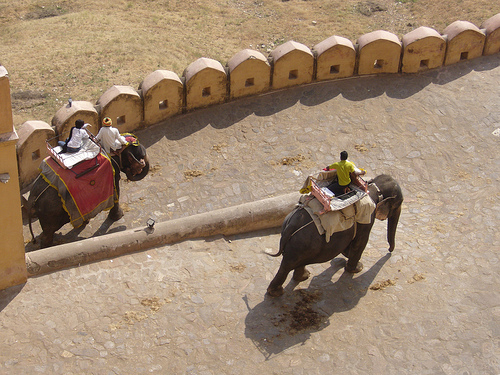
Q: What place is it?
A: It is a walkway.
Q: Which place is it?
A: It is a walkway.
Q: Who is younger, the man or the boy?
A: The boy is younger than the man.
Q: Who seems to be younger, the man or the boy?
A: The boy is younger than the man.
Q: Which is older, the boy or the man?
A: The man is older than the boy.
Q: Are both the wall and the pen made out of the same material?
A: Yes, both the wall and the pen are made of concrete.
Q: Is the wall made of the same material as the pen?
A: Yes, both the wall and the pen are made of concrete.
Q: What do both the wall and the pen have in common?
A: The material, both the wall and the pen are concrete.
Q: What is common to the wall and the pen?
A: The material, both the wall and the pen are concrete.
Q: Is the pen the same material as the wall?
A: Yes, both the pen and the wall are made of cement.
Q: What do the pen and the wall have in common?
A: The material, both the pen and the wall are concrete.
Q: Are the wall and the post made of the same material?
A: No, the wall is made of cement and the post is made of wood.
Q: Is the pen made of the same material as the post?
A: No, the pen is made of cement and the post is made of wood.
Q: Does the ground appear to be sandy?
A: Yes, the ground is sandy.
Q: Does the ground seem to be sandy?
A: Yes, the ground is sandy.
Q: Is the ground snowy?
A: No, the ground is sandy.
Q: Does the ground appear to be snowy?
A: No, the ground is sandy.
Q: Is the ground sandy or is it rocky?
A: The ground is sandy.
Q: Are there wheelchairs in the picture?
A: No, there are no wheelchairs.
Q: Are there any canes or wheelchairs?
A: No, there are no wheelchairs or canes.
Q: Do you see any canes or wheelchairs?
A: No, there are no wheelchairs or canes.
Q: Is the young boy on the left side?
A: Yes, the boy is on the left of the image.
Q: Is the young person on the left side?
A: Yes, the boy is on the left of the image.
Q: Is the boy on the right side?
A: No, the boy is on the left of the image.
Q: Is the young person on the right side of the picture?
A: No, the boy is on the left of the image.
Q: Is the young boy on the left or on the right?
A: The boy is on the left of the image.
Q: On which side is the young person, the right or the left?
A: The boy is on the left of the image.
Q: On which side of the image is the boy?
A: The boy is on the left of the image.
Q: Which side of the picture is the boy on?
A: The boy is on the left of the image.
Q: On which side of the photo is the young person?
A: The boy is on the left of the image.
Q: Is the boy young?
A: Yes, the boy is young.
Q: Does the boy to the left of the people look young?
A: Yes, the boy is young.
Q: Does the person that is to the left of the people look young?
A: Yes, the boy is young.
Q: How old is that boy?
A: The boy is young.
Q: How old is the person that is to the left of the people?
A: The boy is young.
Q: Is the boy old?
A: No, the boy is young.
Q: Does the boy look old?
A: No, the boy is young.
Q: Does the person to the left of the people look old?
A: No, the boy is young.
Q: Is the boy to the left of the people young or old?
A: The boy is young.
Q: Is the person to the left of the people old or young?
A: The boy is young.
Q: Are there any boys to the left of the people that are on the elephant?
A: Yes, there is a boy to the left of the people.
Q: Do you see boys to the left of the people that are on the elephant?
A: Yes, there is a boy to the left of the people.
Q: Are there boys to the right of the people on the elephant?
A: No, the boy is to the left of the people.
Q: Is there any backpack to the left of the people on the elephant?
A: No, there is a boy to the left of the people.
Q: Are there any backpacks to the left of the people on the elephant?
A: No, there is a boy to the left of the people.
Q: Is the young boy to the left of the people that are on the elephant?
A: Yes, the boy is to the left of the people.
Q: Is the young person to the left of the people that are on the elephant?
A: Yes, the boy is to the left of the people.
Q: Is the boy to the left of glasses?
A: No, the boy is to the left of the people.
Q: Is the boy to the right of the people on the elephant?
A: No, the boy is to the left of the people.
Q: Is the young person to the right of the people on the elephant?
A: No, the boy is to the left of the people.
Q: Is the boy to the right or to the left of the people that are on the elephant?
A: The boy is to the left of the people.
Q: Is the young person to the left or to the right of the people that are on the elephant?
A: The boy is to the left of the people.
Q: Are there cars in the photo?
A: No, there are no cars.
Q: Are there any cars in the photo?
A: No, there are no cars.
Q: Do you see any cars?
A: No, there are no cars.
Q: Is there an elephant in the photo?
A: Yes, there is an elephant.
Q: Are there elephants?
A: Yes, there is an elephant.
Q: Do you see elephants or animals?
A: Yes, there is an elephant.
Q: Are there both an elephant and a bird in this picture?
A: No, there is an elephant but no birds.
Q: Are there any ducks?
A: No, there are no ducks.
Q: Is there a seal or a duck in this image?
A: No, there are no ducks or seals.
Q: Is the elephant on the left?
A: Yes, the elephant is on the left of the image.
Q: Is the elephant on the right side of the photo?
A: No, the elephant is on the left of the image.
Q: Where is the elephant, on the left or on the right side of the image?
A: The elephant is on the left of the image.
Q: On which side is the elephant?
A: The elephant is on the left of the image.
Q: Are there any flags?
A: No, there are no flags.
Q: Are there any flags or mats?
A: No, there are no flags or mats.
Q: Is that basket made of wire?
A: Yes, the basket is made of wire.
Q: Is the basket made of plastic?
A: No, the basket is made of wire.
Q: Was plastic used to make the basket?
A: No, the basket is made of wire.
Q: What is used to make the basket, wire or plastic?
A: The basket is made of wire.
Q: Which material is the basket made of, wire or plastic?
A: The basket is made of wire.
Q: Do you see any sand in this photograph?
A: Yes, there is sand.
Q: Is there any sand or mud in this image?
A: Yes, there is sand.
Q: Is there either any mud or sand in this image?
A: Yes, there is sand.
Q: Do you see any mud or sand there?
A: Yes, there is sand.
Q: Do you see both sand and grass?
A: Yes, there are both sand and grass.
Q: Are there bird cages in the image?
A: No, there are no bird cages.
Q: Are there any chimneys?
A: No, there are no chimneys.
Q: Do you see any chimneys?
A: No, there are no chimneys.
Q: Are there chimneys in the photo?
A: No, there are no chimneys.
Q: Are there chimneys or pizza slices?
A: No, there are no chimneys or pizza slices.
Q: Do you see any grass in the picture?
A: Yes, there is grass.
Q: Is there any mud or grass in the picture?
A: Yes, there is grass.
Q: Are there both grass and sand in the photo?
A: Yes, there are both grass and sand.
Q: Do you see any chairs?
A: No, there are no chairs.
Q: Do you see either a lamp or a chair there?
A: No, there are no chairs or lamps.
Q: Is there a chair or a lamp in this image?
A: No, there are no chairs or lamps.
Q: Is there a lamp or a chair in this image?
A: No, there are no chairs or lamps.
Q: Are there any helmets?
A: No, there are no helmets.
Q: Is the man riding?
A: Yes, the man is riding.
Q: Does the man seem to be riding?
A: Yes, the man is riding.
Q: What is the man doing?
A: The man is riding.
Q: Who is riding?
A: The man is riding.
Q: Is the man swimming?
A: No, the man is riding.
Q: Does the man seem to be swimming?
A: No, the man is riding.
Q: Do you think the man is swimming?
A: No, the man is riding.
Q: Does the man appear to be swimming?
A: No, the man is riding.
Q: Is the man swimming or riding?
A: The man is riding.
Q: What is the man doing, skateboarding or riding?
A: The man is riding.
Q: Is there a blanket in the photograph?
A: Yes, there is a blanket.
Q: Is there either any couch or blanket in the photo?
A: Yes, there is a blanket.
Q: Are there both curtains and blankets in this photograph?
A: No, there is a blanket but no curtains.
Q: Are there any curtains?
A: No, there are no curtains.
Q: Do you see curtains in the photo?
A: No, there are no curtains.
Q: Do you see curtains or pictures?
A: No, there are no curtains or pictures.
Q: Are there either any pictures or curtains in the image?
A: No, there are no curtains or pictures.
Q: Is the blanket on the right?
A: No, the blanket is on the left of the image.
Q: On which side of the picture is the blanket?
A: The blanket is on the left of the image.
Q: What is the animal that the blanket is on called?
A: The animal is an elephant.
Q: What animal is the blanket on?
A: The blanket is on the elephant.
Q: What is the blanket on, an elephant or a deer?
A: The blanket is on an elephant.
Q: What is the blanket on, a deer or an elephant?
A: The blanket is on an elephant.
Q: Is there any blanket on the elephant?
A: Yes, there is a blanket on the elephant.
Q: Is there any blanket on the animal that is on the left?
A: Yes, there is a blanket on the elephant.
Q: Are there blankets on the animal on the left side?
A: Yes, there is a blanket on the elephant.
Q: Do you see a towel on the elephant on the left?
A: No, there is a blanket on the elephant.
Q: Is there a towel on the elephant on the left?
A: No, there is a blanket on the elephant.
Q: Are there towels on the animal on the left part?
A: No, there is a blanket on the elephant.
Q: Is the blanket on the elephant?
A: Yes, the blanket is on the elephant.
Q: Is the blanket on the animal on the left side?
A: Yes, the blanket is on the elephant.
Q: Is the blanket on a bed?
A: No, the blanket is on the elephant.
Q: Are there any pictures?
A: No, there are no pictures.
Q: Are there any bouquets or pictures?
A: No, there are no pictures or bouquets.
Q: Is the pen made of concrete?
A: Yes, the pen is made of concrete.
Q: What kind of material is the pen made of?
A: The pen is made of cement.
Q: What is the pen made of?
A: The pen is made of concrete.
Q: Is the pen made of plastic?
A: No, the pen is made of cement.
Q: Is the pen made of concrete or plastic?
A: The pen is made of concrete.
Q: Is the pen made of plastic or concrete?
A: The pen is made of concrete.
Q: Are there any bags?
A: No, there are no bags.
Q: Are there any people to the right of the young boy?
A: Yes, there are people to the right of the boy.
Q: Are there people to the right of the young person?
A: Yes, there are people to the right of the boy.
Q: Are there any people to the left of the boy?
A: No, the people are to the right of the boy.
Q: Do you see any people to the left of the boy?
A: No, the people are to the right of the boy.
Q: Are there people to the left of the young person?
A: No, the people are to the right of the boy.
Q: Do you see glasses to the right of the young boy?
A: No, there are people to the right of the boy.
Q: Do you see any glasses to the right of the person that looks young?
A: No, there are people to the right of the boy.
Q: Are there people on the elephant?
A: Yes, there are people on the elephant.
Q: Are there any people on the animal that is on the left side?
A: Yes, there are people on the elephant.